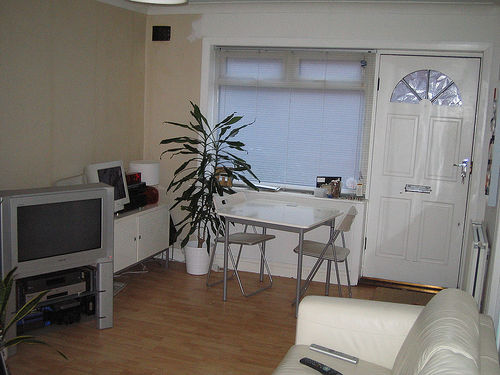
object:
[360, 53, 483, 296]
door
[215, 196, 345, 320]
table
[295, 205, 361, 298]
chair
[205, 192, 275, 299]
chair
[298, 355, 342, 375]
remote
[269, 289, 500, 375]
couch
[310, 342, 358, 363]
remote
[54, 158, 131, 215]
monitor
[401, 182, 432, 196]
mail slot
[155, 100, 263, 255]
plant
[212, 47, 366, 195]
blinds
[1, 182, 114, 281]
tv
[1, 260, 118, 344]
stand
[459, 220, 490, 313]
vent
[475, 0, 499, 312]
wall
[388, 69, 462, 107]
window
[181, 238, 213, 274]
pot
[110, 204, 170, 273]
shelf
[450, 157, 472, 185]
knob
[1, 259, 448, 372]
floor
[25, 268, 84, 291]
vcr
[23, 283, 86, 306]
dvd player